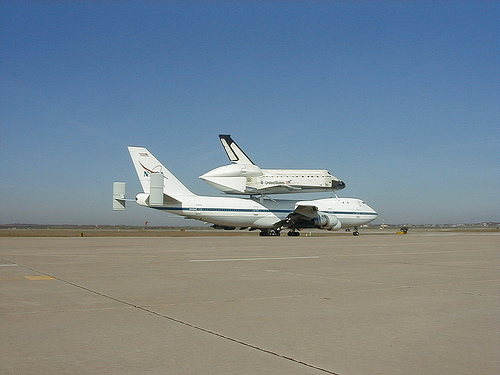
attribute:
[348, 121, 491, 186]
clouds — white 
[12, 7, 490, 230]
sky — blue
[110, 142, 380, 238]
plane — white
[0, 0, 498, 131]
sky — blue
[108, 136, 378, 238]
airplane — white , NASA 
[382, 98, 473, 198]
clouds — white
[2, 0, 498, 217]
sky — blue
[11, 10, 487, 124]
sky — clear, blue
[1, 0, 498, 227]
blue sky — blue 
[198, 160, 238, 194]
protector — white, tail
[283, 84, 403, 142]
clouds — white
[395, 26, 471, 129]
sky — blue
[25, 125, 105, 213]
clouds — white 